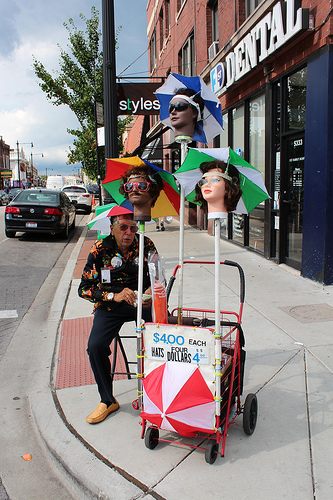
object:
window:
[285, 71, 306, 256]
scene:
[0, 1, 332, 500]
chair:
[110, 285, 172, 397]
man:
[76, 212, 168, 425]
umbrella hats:
[170, 143, 272, 219]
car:
[3, 189, 76, 245]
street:
[0, 201, 91, 496]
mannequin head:
[166, 86, 204, 144]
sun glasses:
[167, 101, 190, 112]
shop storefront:
[212, 0, 308, 276]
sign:
[208, 0, 302, 98]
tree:
[29, 6, 135, 207]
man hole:
[277, 299, 332, 324]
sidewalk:
[28, 210, 332, 500]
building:
[145, 1, 333, 287]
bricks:
[310, 0, 329, 22]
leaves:
[69, 63, 96, 111]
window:
[269, 79, 282, 259]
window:
[244, 98, 264, 206]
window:
[147, 29, 157, 73]